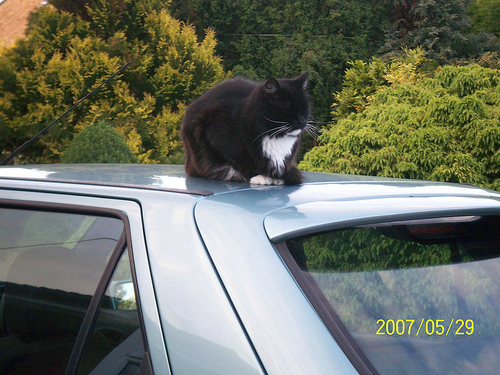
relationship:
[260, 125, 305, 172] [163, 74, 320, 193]
fur under cat's mouth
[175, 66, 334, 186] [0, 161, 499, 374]
cat on car